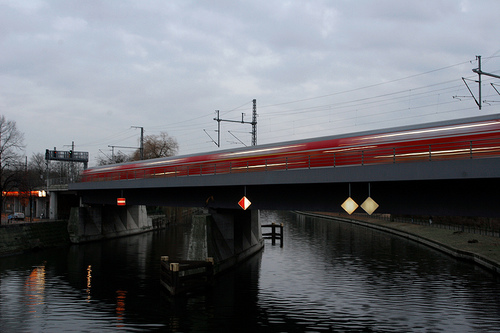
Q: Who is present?
A: Nobody.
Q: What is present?
A: A bridge.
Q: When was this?
A: Daytime.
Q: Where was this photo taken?
A: Near a bridge.